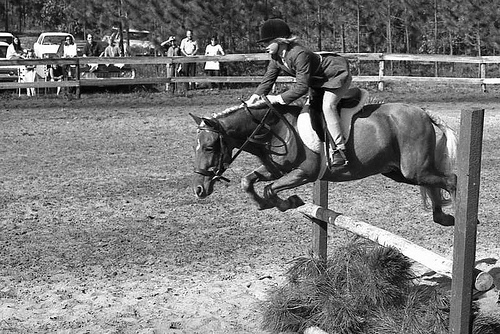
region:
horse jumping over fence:
[173, 95, 483, 234]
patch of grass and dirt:
[118, 291, 144, 313]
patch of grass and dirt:
[253, 254, 290, 289]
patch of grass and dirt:
[93, 203, 126, 231]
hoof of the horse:
[287, 196, 303, 217]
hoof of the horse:
[442, 215, 482, 229]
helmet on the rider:
[252, 14, 298, 44]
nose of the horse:
[197, 175, 213, 210]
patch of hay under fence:
[346, 281, 385, 313]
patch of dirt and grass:
[168, 235, 195, 266]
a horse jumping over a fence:
[181, 23, 477, 275]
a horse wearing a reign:
[180, 105, 370, 210]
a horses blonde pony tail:
[391, 95, 481, 207]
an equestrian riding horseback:
[236, 18, 365, 175]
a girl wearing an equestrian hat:
[250, 14, 287, 59]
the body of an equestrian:
[260, 52, 377, 183]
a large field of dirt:
[70, 192, 222, 305]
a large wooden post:
[293, 164, 494, 326]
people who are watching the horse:
[23, 31, 167, 89]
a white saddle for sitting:
[289, 109, 361, 164]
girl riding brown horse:
[195, 11, 478, 255]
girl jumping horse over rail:
[188, 8, 488, 284]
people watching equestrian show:
[6, 15, 493, 300]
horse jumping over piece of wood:
[184, 8, 476, 251]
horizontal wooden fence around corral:
[16, 32, 251, 125]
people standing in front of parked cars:
[3, 25, 219, 88]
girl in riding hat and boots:
[251, 12, 360, 209]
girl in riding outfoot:
[246, 13, 383, 223]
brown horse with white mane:
[183, 87, 298, 209]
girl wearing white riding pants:
[255, 13, 382, 188]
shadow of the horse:
[306, 200, 349, 229]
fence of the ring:
[5, 38, 490, 123]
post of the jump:
[418, 101, 488, 332]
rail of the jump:
[263, 179, 496, 293]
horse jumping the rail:
[146, 39, 478, 266]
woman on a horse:
[237, 15, 386, 218]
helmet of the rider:
[246, 13, 308, 48]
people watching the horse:
[0, 17, 243, 103]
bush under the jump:
[258, 242, 450, 330]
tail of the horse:
[421, 96, 463, 191]